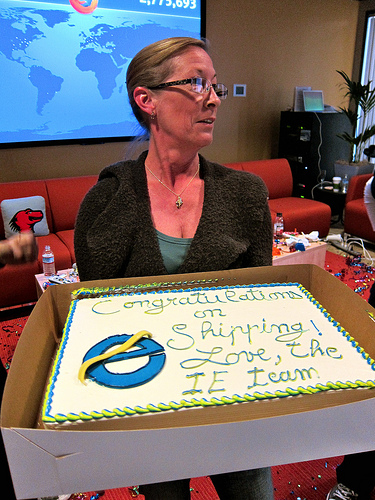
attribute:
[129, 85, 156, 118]
ear — red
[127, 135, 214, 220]
necklace — gold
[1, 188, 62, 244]
pillow — white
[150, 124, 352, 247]
couch — red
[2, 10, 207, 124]
map — distant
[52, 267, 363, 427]
cake — white, blue, yellow 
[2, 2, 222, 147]
screen — large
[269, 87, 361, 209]
cabinet — black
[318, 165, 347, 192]
cup — white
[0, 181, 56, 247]
pillow — white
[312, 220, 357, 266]
wires — white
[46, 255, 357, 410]
cake — blue, white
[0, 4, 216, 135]
picture — blue, white, red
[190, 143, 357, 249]
couch — red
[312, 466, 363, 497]
shoe — grey, white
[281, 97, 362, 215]
cabinet — black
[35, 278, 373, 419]
sheet cake — Large  , white 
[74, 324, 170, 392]
letter e — Blue , yellow  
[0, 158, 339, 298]
couch — long , red